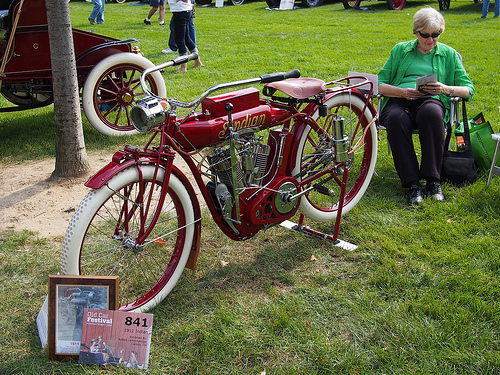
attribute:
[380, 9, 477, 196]
lady — reading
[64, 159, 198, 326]
tire — white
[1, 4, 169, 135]
car — old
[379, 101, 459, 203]
pants —  black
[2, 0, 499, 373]
grass — green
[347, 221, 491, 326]
grass — green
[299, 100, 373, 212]
rim — red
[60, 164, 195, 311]
tire — REAR, white, red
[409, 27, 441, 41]
sunglasses — dark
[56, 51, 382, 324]
motorcycle — Old, red 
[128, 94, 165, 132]
headlight — chromed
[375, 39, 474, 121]
shirt — green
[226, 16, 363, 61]
grass — green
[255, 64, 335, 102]
seat — red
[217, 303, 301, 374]
grass — patch, green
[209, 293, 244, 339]
grass — green, patch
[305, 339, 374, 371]
grass — green, patch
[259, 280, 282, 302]
grass — green, patch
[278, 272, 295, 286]
grass — green, patch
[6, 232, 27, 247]
grass — green, patch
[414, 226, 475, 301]
grass — green, patch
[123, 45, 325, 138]
long handlebars —  LONG 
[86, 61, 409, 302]
bicycle — red, white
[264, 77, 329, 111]
bicycle seat — red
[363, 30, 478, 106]
shirt — green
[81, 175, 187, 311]
rim — red